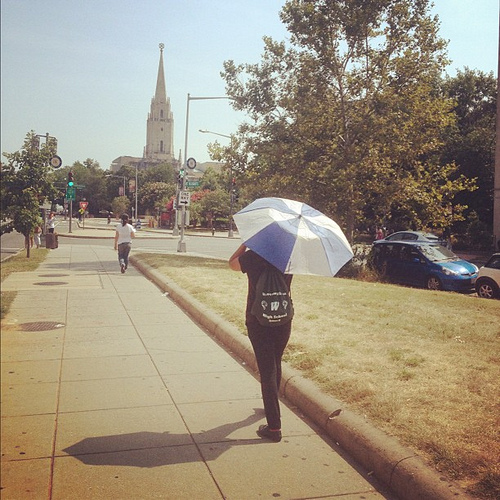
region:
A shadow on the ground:
[63, 406, 264, 467]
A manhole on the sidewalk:
[14, 319, 64, 332]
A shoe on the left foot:
[257, 423, 282, 440]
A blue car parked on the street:
[368, 239, 475, 289]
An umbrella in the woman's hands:
[231, 197, 353, 279]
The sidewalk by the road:
[2, 247, 395, 497]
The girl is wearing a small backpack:
[251, 273, 295, 326]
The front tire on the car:
[424, 271, 440, 288]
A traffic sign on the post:
[176, 189, 192, 208]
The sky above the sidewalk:
[1, 2, 495, 169]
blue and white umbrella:
[243, 196, 363, 275]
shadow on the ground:
[46, 417, 253, 459]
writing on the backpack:
[267, 283, 294, 330]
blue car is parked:
[372, 247, 466, 295]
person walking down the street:
[112, 209, 140, 280]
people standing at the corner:
[35, 200, 52, 265]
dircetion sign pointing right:
[180, 184, 198, 217]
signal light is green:
[53, 152, 83, 211]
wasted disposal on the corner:
[43, 232, 68, 259]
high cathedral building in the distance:
[143, 48, 173, 179]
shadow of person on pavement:
[61, 429, 221, 465]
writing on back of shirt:
[251, 285, 292, 331]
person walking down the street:
[93, 209, 159, 281]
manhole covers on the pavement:
[26, 262, 63, 350]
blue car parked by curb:
[365, 243, 457, 299]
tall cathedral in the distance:
[153, 31, 166, 158]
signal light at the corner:
[59, 156, 81, 242]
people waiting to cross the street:
[31, 212, 80, 252]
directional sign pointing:
[160, 180, 206, 217]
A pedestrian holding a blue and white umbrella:
[223, 184, 361, 453]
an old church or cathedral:
[109, 38, 209, 202]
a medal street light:
[178, 78, 240, 252]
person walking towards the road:
[107, 210, 142, 280]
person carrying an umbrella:
[218, 193, 356, 443]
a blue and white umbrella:
[228, 178, 360, 281]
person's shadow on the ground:
[50, 405, 289, 470]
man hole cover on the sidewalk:
[11, 313, 76, 337]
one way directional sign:
[172, 185, 194, 212]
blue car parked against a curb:
[366, 233, 498, 296]